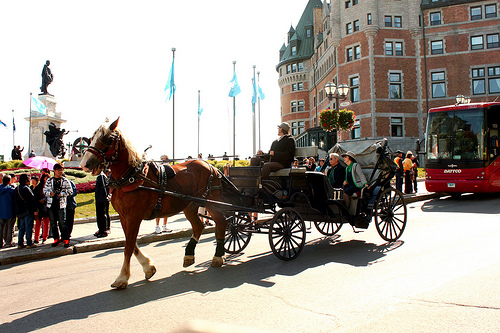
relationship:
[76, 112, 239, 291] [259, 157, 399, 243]
horse pulling carriage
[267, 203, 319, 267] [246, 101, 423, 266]
wheel under carriage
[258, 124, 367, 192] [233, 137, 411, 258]
people riding carriage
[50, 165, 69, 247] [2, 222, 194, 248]
people standing on sidewalk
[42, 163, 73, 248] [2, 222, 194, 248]
people standing on sidewalk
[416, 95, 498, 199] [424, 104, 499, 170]
bus has front window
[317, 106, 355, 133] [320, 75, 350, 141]
flowers hang from street lamp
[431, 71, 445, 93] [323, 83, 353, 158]
light on lamp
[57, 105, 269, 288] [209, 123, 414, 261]
horse pulling carriage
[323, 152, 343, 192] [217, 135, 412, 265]
passenger riding in carriage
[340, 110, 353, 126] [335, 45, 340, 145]
lamps on poles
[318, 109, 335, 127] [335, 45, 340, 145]
lamps on poles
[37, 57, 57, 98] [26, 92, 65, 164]
statue atop pedestal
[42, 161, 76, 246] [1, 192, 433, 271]
man standing on curb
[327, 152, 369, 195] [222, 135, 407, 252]
people sitting in carriage